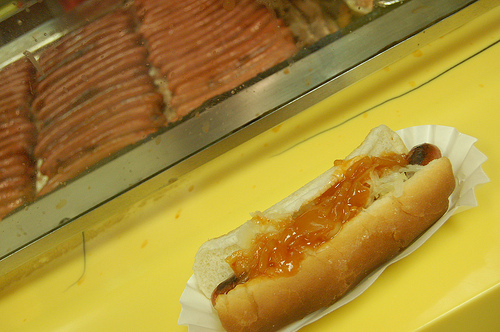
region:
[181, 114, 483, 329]
hot dog in a white wrapper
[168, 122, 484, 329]
hot dog topped with toppings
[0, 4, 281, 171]
hot dogs cooking on rack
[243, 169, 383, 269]
mustard on top of hot dog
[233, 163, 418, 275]
sour kroute on hot dog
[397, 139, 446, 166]
burnt tip of hot dog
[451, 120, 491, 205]
white paper holder for hot dog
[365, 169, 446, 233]
brown hot dog bun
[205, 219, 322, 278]
ketchup on top of hot dog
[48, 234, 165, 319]
yellow counter by hot dog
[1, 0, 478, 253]
A glass display case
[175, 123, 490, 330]
A paper hot dog holder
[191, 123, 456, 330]
A hot dog with several condiments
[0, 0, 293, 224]
Some hot dogs being cooked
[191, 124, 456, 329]
A hot dog bun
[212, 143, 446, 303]
A hot dog in a bun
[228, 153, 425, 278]
some sauerkraut on the hot dog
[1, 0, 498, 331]
A yellow counter top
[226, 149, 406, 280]
A red sauce on the hot dog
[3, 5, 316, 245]
some grease specs on the glass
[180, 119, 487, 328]
hot dog on a bun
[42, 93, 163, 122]
hot dogs on a grill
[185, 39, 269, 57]
hot dog on grill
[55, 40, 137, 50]
hot dog on grill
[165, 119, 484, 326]
hot dog on a counter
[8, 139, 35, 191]
hot dog on a grill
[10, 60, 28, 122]
hot dog on a grill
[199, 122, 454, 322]
bun on a tray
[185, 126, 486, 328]
white tray with a hot dog on top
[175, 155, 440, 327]
sauce on a hot dog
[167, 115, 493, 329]
hot dog on a yellow counter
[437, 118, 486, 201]
hot dog in a wrapper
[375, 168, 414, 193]
onions on a hot dog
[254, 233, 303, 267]
sauce on a hot dog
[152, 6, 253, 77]
hot dogs in a warmer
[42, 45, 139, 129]
hot dogs in a warmer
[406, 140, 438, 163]
wiener sticking out of a hot dog bun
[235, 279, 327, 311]
hot dog bun a a wrapper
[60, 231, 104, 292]
grey mark on the yellow counter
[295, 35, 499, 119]
grey mark on the yellow counter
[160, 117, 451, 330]
grilled hotdog with grilled onions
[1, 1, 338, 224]
many hot dogs in grill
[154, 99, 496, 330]
grilled hot dog sitting on yellow counter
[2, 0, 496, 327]
grilled hot dog in white paper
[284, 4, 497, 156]
crack in yellow counter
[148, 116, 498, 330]
tip of hot dog is black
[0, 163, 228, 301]
paint worn in crack of counter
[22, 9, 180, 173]
row of grilled hot dogs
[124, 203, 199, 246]
stains on yellow counter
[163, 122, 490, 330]
hot dog with grilled onions and sourkraut